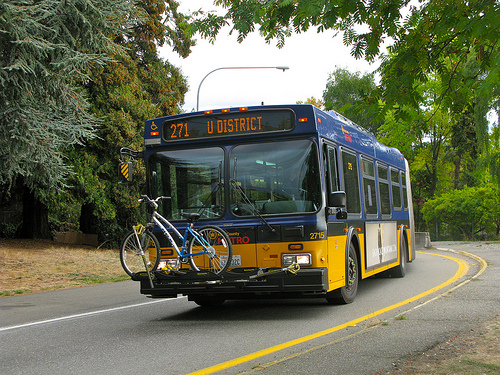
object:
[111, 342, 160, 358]
pavement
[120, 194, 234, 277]
bike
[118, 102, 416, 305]
bus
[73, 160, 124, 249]
tree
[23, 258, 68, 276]
dirt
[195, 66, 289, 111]
street light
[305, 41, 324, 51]
sky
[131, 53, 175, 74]
leaves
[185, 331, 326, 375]
lines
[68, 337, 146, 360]
road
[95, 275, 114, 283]
grass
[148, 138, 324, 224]
windshield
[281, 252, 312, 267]
head light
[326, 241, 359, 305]
tire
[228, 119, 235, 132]
words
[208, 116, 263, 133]
sign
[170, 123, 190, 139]
number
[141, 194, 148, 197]
handlebars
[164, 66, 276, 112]
pole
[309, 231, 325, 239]
symbol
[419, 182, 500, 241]
bushes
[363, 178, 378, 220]
window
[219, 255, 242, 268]
license plate